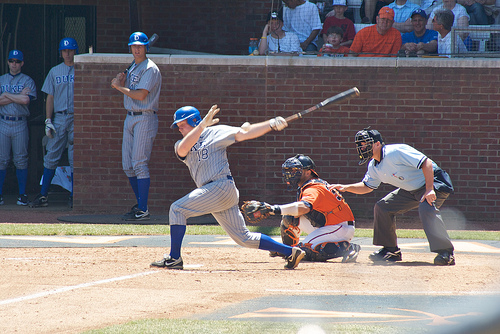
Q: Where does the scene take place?
A: At a baseball game.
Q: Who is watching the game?
A: Spectators.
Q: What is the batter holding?
A: Bat.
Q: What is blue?
A: Helmets.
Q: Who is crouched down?
A: Catcher.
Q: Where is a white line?
A: On the dirt.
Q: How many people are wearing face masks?
A: Two.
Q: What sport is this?
A: Baseball.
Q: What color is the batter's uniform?
A: Blue and grey.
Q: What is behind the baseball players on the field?
A: Brick wall.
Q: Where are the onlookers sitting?
A: Bleachers.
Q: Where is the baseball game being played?
A: Baseball field.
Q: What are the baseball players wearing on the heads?
A: Helmets.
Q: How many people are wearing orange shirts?
A: One.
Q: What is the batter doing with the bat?
A: Throwing the bat.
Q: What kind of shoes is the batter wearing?
A: Sneakers.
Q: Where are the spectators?
A: Behind the fence.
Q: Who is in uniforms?
A: Baseball players.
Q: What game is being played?
A: Baseball.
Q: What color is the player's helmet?
A: Blue.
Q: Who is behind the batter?
A: The catcher and umpire.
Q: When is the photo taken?
A: In the daytime.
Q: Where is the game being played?
A: At a baseball field.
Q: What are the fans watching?
A: The baseball game.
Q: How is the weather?
A: It's sunny.